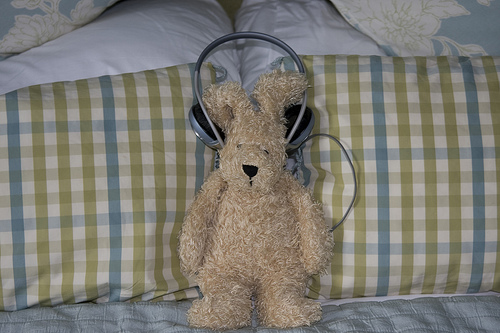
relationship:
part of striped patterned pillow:
[362, 198, 465, 293] [373, 116, 453, 170]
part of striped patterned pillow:
[63, 155, 138, 303] [30, 221, 140, 320]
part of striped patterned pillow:
[362, 198, 465, 293] [369, 104, 498, 288]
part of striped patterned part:
[63, 155, 138, 303] [63, 155, 138, 303]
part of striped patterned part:
[362, 198, 465, 293] [362, 198, 465, 293]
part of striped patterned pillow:
[332, 177, 492, 233] [364, 150, 473, 329]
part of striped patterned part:
[32, 174, 105, 317] [63, 155, 138, 303]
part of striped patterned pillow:
[32, 174, 105, 317] [40, 212, 120, 313]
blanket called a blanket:
[35, 269, 167, 333] [0, 302, 168, 333]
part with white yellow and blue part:
[63, 155, 138, 303] [63, 155, 138, 303]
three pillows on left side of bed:
[421, 116, 472, 193] [460, 112, 498, 154]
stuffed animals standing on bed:
[169, 142, 326, 324] [3, 108, 483, 289]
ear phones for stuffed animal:
[187, 30, 316, 150] [174, 151, 332, 333]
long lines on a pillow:
[40, 198, 109, 307] [34, 254, 191, 281]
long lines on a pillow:
[40, 198, 109, 307] [35, 144, 158, 333]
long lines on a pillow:
[372, 258, 432, 333] [363, 115, 449, 304]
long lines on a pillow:
[40, 198, 109, 307] [42, 144, 168, 333]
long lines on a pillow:
[40, 198, 111, 326] [34, 240, 129, 290]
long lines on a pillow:
[40, 198, 109, 307] [350, 212, 444, 333]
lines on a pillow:
[281, 60, 497, 305] [268, 49, 491, 296]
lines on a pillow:
[288, 133, 357, 233] [268, 49, 491, 296]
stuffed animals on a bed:
[174, 73, 337, 330] [3, 5, 495, 330]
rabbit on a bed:
[179, 69, 331, 329] [3, 5, 495, 330]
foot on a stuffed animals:
[188, 294, 253, 326] [174, 73, 337, 330]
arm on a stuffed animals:
[179, 169, 219, 267] [174, 73, 337, 330]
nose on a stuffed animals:
[239, 163, 259, 175] [174, 73, 337, 330]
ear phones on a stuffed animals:
[188, 29, 315, 150] [174, 73, 337, 330]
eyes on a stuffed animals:
[236, 143, 272, 155] [174, 73, 337, 330]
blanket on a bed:
[0, 302, 168, 333] [3, 5, 495, 330]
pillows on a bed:
[1, 5, 386, 95] [3, 5, 495, 330]